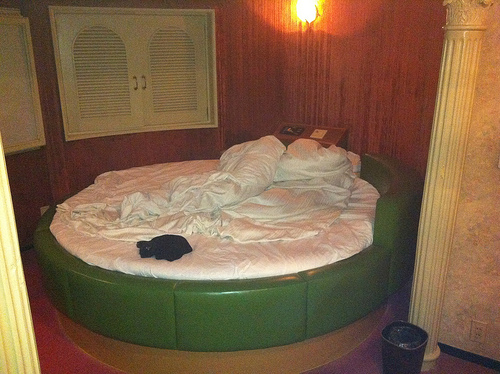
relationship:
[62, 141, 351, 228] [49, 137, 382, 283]
pile in blankets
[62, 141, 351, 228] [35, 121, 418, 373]
pile on bed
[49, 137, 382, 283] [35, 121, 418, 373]
blankets on bed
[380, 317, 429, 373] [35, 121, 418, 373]
can next to bed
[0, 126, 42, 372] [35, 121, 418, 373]
column near bed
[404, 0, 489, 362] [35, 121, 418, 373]
column near bed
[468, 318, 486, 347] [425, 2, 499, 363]
socket on paper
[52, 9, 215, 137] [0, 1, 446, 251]
shutters on walls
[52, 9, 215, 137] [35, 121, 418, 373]
shutters near bed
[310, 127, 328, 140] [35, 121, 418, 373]
notebook controls bed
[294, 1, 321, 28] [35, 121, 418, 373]
light over bed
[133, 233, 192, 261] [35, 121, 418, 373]
cat on bed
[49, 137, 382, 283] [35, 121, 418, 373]
blankets on top of bed